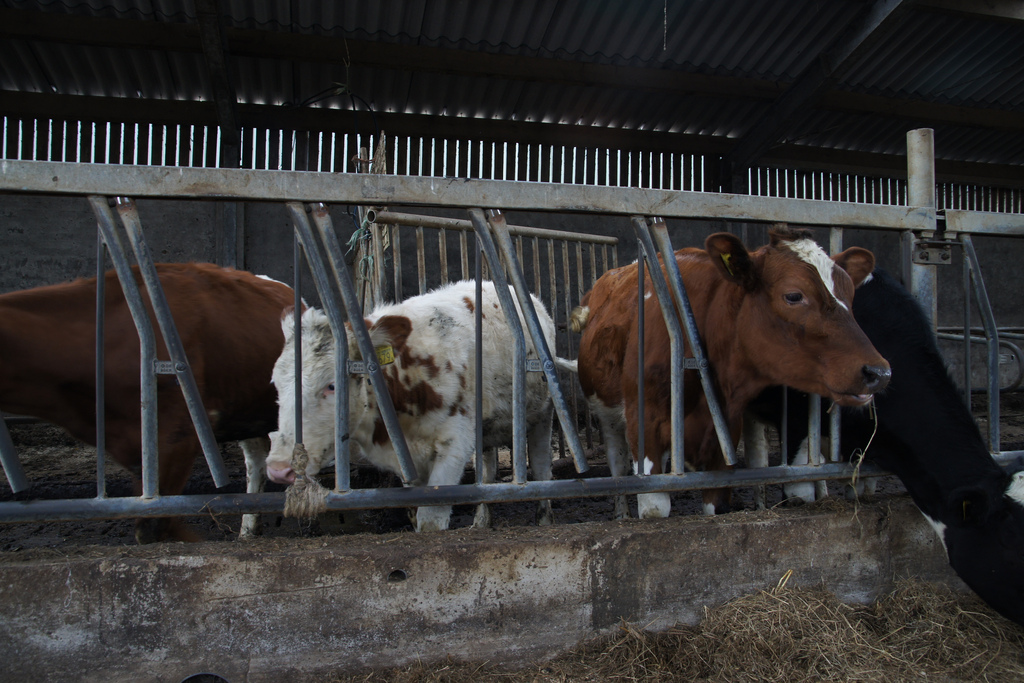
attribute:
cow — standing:
[6, 250, 281, 480]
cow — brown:
[574, 234, 907, 490]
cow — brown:
[255, 264, 569, 558]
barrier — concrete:
[26, 487, 962, 641]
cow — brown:
[8, 238, 311, 524]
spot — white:
[765, 215, 854, 304]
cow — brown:
[561, 230, 899, 509]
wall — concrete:
[19, 497, 946, 645]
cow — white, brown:
[272, 209, 640, 514]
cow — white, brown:
[141, 201, 580, 491]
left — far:
[2, 7, 240, 679]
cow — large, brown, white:
[514, 232, 849, 513]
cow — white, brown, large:
[276, 279, 583, 545]